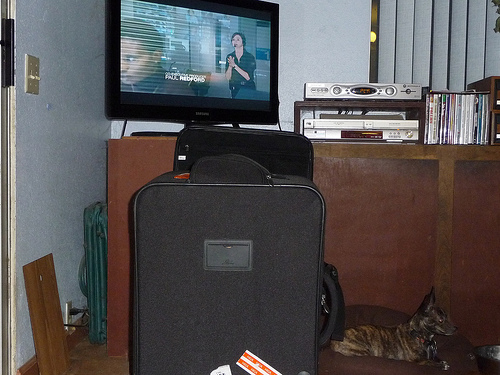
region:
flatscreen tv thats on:
[111, 8, 291, 128]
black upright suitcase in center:
[124, 148, 337, 367]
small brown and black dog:
[336, 278, 459, 370]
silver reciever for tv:
[301, 75, 427, 106]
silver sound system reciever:
[294, 105, 424, 148]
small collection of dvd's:
[425, 85, 492, 156]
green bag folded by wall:
[74, 207, 111, 360]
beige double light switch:
[22, 55, 42, 92]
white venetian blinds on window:
[371, 12, 489, 82]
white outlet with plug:
[60, 300, 79, 332]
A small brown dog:
[325, 286, 459, 367]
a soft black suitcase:
[130, 155, 340, 371]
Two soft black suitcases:
[131, 120, 332, 370]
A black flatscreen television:
[101, 0, 276, 123]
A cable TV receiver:
[304, 81, 421, 98]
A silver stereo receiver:
[302, 117, 419, 139]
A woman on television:
[224, 31, 256, 98]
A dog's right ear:
[420, 287, 438, 312]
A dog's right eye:
[436, 316, 443, 323]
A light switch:
[25, 54, 41, 96]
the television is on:
[99, 3, 297, 125]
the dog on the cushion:
[314, 288, 484, 374]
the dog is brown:
[345, 282, 457, 372]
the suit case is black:
[106, 111, 346, 373]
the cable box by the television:
[304, 73, 419, 99]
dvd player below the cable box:
[299, 113, 417, 145]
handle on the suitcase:
[316, 264, 354, 352]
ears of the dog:
[411, 294, 440, 311]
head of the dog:
[411, 283, 468, 348]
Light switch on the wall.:
[2, 24, 72, 126]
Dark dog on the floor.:
[304, 292, 446, 373]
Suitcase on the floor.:
[96, 137, 393, 370]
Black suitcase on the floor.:
[39, 130, 337, 365]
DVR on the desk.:
[286, 56, 428, 171]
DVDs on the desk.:
[416, 72, 499, 156]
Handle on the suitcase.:
[262, 209, 376, 340]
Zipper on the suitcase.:
[316, 272, 351, 342]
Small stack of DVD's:
[425, 90, 490, 145]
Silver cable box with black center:
[300, 80, 421, 105]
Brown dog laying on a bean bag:
[315, 285, 480, 370]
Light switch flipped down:
[16, 50, 46, 95]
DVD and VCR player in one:
[297, 112, 422, 142]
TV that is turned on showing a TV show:
[100, 0, 285, 127]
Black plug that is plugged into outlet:
[60, 295, 90, 331]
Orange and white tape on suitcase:
[231, 340, 278, 370]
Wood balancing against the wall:
[20, 245, 67, 372]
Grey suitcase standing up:
[133, 123, 344, 371]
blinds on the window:
[373, 9, 465, 84]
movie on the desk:
[424, 105, 445, 120]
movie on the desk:
[439, 92, 452, 137]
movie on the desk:
[439, 96, 452, 143]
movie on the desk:
[457, 91, 471, 125]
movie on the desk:
[466, 101, 478, 131]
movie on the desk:
[463, 101, 473, 153]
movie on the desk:
[480, 86, 486, 136]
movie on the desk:
[448, 90, 462, 146]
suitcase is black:
[126, 147, 343, 374]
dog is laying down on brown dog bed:
[318, 284, 476, 374]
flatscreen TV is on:
[103, 1, 280, 140]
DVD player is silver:
[301, 115, 421, 144]